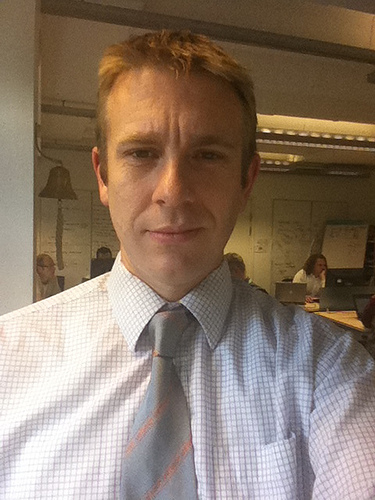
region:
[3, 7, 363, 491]
white man standing in front of camera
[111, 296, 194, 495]
grey tie with red stripe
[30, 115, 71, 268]
bell hanging on a wall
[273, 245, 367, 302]
woman sitting at desk behind computer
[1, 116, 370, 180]
overhead lights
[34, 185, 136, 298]
writing on a whiteboard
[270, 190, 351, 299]
writing on a whiteboard behind woman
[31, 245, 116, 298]
two men working in the back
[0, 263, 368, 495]
man wearing pink checkered shirt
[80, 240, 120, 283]
man behind computer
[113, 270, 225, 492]
man is wearing a tie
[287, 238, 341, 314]
man is working on laptop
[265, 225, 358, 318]
man is working on laptop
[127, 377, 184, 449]
stripe in the tie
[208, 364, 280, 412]
small grey checkered pattern on shirt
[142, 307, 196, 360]
the tie is knotted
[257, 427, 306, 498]
pocket in the shirt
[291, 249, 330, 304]
person in the background on computer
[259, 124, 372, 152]
overhead lights behind man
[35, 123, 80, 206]
bell hanging on wall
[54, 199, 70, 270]
long tassel hanging from bell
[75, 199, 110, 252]
writing on the board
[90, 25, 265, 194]
short blonde hair on man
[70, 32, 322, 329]
the head of a man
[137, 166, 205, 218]
the nose of a man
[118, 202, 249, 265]
the lips of a man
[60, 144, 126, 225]
the ears of a man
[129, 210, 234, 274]
the mouth of a man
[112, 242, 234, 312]
the chin of a man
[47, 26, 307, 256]
the hair of a man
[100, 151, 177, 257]
the cheek of a man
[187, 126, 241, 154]
the eye brow of a man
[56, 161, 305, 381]
a man wearing a shirt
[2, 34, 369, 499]
Man with a dress shirt and necktie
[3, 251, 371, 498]
white and gray dress shirt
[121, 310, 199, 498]
gray necktie with pink stripes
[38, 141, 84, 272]
bell mounted to the wall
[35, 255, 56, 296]
balding man with glasses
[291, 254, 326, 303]
man with long hair and hand over mouth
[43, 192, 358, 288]
several white boards on the back wall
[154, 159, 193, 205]
the man with a tie's nose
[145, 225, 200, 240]
the man with a tie's mouth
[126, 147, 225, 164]
man with a tie's eyes